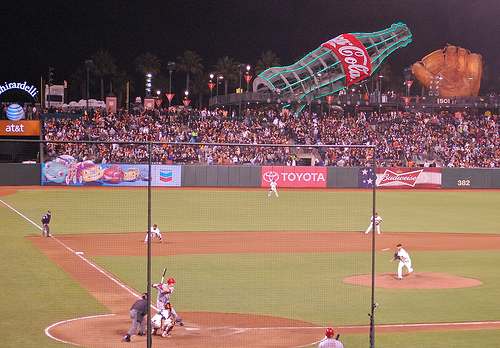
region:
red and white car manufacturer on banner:
[254, 161, 332, 188]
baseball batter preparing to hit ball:
[149, 263, 188, 330]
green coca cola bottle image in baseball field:
[250, 21, 417, 113]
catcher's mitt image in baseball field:
[405, 43, 488, 99]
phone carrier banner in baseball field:
[1, 95, 38, 137]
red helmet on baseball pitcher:
[164, 276, 179, 287]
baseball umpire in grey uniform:
[117, 284, 151, 344]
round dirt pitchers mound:
[341, 265, 486, 300]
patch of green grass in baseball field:
[78, 189, 235, 219]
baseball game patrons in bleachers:
[46, 116, 494, 161]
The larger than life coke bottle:
[250, 18, 415, 113]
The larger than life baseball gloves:
[410, 43, 482, 107]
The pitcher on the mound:
[387, 243, 416, 278]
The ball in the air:
[377, 243, 392, 254]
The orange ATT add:
[0, 118, 39, 140]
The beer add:
[357, 161, 442, 193]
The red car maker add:
[260, 161, 327, 192]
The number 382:
[453, 176, 474, 188]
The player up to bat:
[149, 264, 189, 326]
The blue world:
[2, 101, 25, 122]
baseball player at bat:
[151, 266, 186, 325]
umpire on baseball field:
[124, 291, 149, 341]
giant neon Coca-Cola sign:
[252, 18, 414, 123]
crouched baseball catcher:
[149, 299, 183, 339]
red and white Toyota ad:
[260, 164, 327, 186]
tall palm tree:
[176, 51, 203, 91]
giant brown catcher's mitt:
[411, 44, 488, 97]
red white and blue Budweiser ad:
[361, 167, 443, 189]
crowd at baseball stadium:
[47, 109, 494, 161]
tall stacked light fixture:
[143, 71, 153, 96]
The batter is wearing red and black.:
[145, 264, 193, 321]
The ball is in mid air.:
[376, 240, 393, 254]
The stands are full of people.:
[93, 112, 366, 161]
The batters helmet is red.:
[163, 275, 180, 286]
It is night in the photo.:
[101, 7, 270, 35]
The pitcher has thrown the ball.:
[370, 235, 435, 292]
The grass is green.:
[199, 262, 286, 306]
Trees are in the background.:
[83, 45, 242, 84]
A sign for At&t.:
[0, 100, 44, 137]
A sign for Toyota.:
[253, 163, 330, 195]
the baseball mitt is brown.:
[407, 39, 487, 105]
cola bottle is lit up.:
[250, 17, 421, 112]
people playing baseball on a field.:
[1, 175, 497, 346]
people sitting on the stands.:
[34, 90, 499, 168]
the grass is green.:
[0, 180, 498, 345]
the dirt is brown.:
[25, 220, 498, 345]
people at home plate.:
[120, 262, 187, 339]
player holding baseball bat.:
[148, 264, 183, 301]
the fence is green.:
[4, 152, 499, 198]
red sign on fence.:
[256, 159, 330, 191]